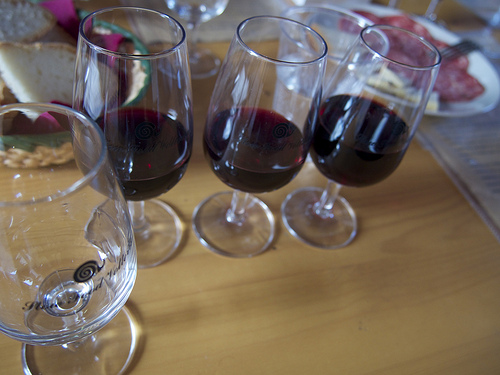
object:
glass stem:
[226, 188, 256, 224]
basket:
[0, 9, 153, 169]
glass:
[271, 4, 391, 163]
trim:
[0, 0, 127, 133]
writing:
[22, 236, 134, 311]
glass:
[0, 103, 138, 374]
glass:
[191, 15, 328, 259]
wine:
[201, 106, 308, 195]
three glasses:
[73, 6, 441, 268]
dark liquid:
[73, 106, 191, 200]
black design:
[73, 259, 99, 283]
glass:
[156, 0, 230, 80]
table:
[0, 0, 499, 374]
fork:
[436, 37, 483, 62]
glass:
[73, 6, 195, 268]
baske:
[0, 7, 152, 168]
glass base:
[188, 189, 277, 259]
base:
[281, 179, 359, 249]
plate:
[312, 4, 499, 118]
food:
[340, 8, 485, 103]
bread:
[0, 40, 121, 123]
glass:
[280, 23, 442, 250]